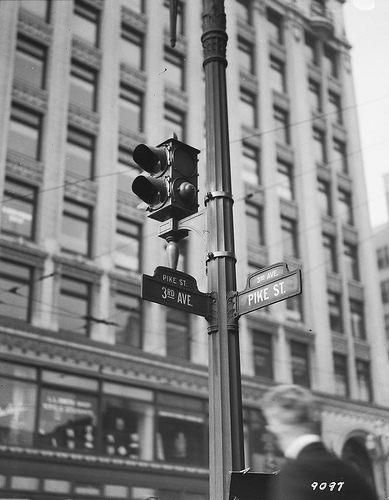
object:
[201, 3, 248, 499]
post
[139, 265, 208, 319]
street sign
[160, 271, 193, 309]
pike st 3rd ave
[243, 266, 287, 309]
3rd ave pike street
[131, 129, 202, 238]
street light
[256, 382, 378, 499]
man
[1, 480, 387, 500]
street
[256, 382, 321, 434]
short hair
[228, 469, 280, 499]
briefcase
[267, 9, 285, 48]
window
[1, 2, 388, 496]
building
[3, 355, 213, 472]
store front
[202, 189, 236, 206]
metal ring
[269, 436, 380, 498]
suit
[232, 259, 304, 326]
two street signs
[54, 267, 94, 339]
many windows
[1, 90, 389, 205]
wires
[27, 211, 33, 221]
words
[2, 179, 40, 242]
window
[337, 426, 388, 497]
entrance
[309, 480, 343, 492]
9097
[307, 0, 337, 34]
balcony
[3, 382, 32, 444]
displays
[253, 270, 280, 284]
3rd ave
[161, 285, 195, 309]
3rd ave